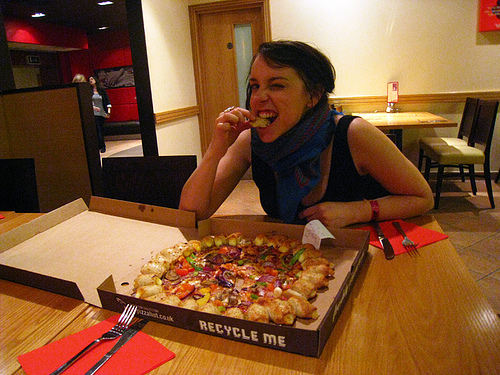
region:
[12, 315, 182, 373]
RED NAPKIN ON THE TABLE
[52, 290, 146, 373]
FORK AND KNIFE ON THE NAPKIN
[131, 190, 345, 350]
PIZZA IS IN THE BOX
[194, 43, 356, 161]
GIRL EATING A PIZZA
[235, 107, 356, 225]
GIRL WEARING BLUE SCARF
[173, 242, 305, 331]
VEGETABLES ALL OVER A PIZZA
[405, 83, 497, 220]
CHAIRS ARE PUSHED IN AT A TABLE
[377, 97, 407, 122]
SALT AND PEPPER ON THE TABLE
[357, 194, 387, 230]
BRACELET ON THE GIRLS WRIST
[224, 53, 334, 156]
the head of a woman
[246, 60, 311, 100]
the eye of a woman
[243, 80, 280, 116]
the nose of a woman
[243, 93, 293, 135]
the mouth of a woman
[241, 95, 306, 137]
the lips of a woman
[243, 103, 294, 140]
the teeth of a woman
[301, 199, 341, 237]
the hand of a woman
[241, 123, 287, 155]
the chin of a woman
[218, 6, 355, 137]
the hair of a woman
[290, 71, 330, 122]
the ear of a woman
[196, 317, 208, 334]
The letter is white.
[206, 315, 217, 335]
The letter is white.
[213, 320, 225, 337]
The letter is white.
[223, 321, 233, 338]
The letter is white.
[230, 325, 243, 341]
The letter is white.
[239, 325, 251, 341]
The letter is white.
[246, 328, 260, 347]
The letter is white.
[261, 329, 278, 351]
The letter is white.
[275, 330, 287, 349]
The letter is white.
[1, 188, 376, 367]
The pizza is in a take-out box.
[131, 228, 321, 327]
pizza in a cardboard box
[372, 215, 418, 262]
fork and knife on a red napkin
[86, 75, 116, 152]
woman wearing a black jacket and blue shirt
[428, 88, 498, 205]
two empty chairs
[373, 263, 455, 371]
wooden table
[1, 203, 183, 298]
lid of a cardboard pizza box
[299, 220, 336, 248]
paper receipt in the pizza box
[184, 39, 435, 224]
woman wearing a sleeveless shirt and blue scarf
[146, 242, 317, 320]
pizza on the table in a box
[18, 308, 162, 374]
silverware on a red napkin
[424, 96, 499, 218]
a restaurant chair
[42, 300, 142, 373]
a long gray fork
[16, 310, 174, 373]
part of a red napkin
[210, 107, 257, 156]
the hand of a woman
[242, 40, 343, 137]
a woman's black hair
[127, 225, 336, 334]
a large pizza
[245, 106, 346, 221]
a blue scarf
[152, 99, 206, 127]
a brown wall trim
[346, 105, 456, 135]
part of a brown table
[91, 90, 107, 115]
part of a woman's blue shirt